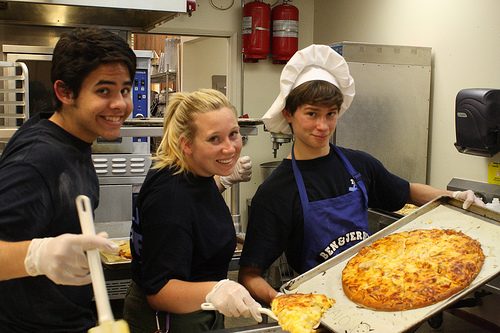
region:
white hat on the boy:
[261, 34, 357, 96]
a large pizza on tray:
[348, 227, 475, 309]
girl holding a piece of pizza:
[201, 284, 327, 331]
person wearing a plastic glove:
[186, 283, 261, 317]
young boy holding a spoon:
[78, 193, 120, 331]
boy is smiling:
[1, 50, 143, 220]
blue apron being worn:
[285, 160, 372, 254]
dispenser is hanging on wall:
[456, 74, 496, 174]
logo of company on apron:
[324, 218, 365, 268]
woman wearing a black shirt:
[126, 177, 238, 279]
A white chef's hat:
[261, 39, 359, 139]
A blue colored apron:
[287, 137, 373, 271]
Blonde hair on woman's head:
[152, 85, 245, 181]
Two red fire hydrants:
[235, 1, 302, 71]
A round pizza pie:
[338, 224, 484, 314]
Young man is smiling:
[44, 18, 137, 145]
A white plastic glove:
[201, 274, 267, 326]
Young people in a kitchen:
[2, 1, 485, 329]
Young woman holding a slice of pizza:
[126, 82, 338, 331]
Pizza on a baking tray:
[277, 189, 498, 330]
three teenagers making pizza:
[37, 33, 463, 330]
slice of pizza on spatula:
[255, 268, 334, 330]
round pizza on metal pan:
[358, 214, 454, 320]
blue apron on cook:
[288, 130, 394, 315]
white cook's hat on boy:
[256, 43, 373, 136]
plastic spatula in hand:
[51, 190, 142, 327]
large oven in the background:
[13, 38, 152, 255]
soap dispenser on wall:
[427, 89, 492, 144]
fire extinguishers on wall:
[248, 8, 306, 77]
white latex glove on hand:
[21, 235, 131, 287]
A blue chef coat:
[290, 148, 375, 263]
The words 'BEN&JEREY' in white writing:
[310, 225, 370, 256]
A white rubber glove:
[22, 226, 122, 286]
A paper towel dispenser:
[445, 80, 495, 155]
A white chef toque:
[235, 30, 390, 140]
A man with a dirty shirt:
[0, 15, 150, 330]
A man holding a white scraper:
[0, 15, 150, 325]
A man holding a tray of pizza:
[250, 30, 495, 330]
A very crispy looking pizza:
[335, 220, 485, 310]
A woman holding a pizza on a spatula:
[122, 70, 329, 330]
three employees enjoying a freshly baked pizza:
[4, 5, 498, 330]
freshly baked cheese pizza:
[339, 225, 482, 310]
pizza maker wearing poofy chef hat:
[237, 41, 482, 331]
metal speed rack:
[0, 61, 32, 128]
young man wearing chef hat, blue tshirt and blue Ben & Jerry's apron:
[238, 43, 484, 309]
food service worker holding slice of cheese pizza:
[128, 83, 334, 332]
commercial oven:
[3, 45, 154, 121]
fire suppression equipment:
[236, 1, 300, 66]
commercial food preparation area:
[5, 2, 497, 331]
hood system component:
[1, 0, 200, 28]